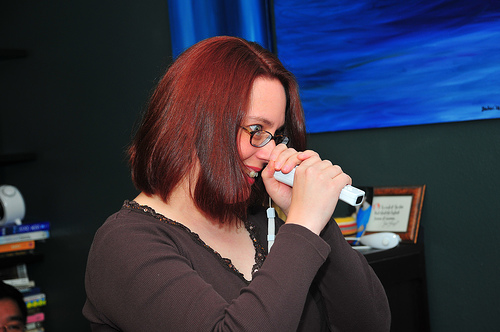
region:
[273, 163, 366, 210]
white nintendo wii remote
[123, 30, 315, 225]
red hair of woman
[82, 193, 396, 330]
black long sleeve shirt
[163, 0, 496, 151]
blue and black painting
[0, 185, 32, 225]
white and black clock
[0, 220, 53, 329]
a tall pile of books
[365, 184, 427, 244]
brown and white picture frame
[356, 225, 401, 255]
white nintendo wii controller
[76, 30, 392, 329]
woman holding wii controller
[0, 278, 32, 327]
head of random guy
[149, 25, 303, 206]
head of a person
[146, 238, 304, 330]
arm of a person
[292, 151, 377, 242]
hand of a person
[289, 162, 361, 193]
fingers of a person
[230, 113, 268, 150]
eye of a person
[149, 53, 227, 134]
hair of a person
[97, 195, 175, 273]
shoulder of a person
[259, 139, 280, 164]
nose of a person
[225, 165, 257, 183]
mouth of a person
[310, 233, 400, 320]
arm of a person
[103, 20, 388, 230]
The woman has reddish brown hair.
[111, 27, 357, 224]
The woman is wearing glasses.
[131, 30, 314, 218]
The woman has a playful smile.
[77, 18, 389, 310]
The woman is having fun.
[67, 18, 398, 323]
The woman is wearing a brown shirt.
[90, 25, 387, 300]
The woman has short brownish red hair.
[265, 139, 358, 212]
The woman's hands are holding a remote control.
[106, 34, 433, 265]
She is holding the remote control to her face.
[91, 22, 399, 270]
She is playing with a remote control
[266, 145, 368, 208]
Wii remote in hand.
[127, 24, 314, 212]
Red hair on woman.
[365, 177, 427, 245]
Picture from on stand.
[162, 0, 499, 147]
Painting on the wall.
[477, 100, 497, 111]
Signature on the painting.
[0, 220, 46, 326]
Books on the shelves.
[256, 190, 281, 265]
Strap to the Wii remote.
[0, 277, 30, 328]
Person behind the woman.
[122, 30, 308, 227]
Glasses on the woman.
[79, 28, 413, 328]
Brown shirt on woman.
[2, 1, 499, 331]
Interior, showing close-up of red-headed woman.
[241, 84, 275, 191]
Pink face, showing open eyes, glasses and toothy smile.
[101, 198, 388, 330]
Long-sleeved shirt with crocheted, vee-shaped neckline.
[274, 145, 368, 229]
Hands, gripping item like telescope.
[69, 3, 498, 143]
Dark wall and blue abstract on wall.